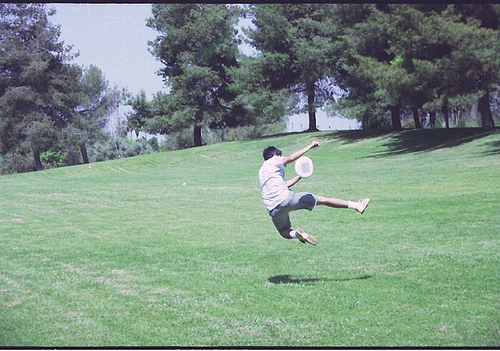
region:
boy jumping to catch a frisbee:
[255, 138, 372, 246]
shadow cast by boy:
[266, 270, 373, 285]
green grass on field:
[2, 130, 497, 348]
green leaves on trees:
[2, 4, 498, 170]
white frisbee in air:
[294, 153, 314, 180]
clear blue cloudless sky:
[2, 1, 354, 153]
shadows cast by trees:
[315, 129, 499, 161]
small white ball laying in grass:
[180, 178, 187, 186]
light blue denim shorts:
[265, 190, 317, 232]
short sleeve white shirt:
[258, 155, 290, 211]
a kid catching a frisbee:
[248, 135, 397, 268]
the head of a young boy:
[259, 139, 286, 164]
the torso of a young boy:
[251, 144, 294, 206]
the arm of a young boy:
[282, 138, 308, 165]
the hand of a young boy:
[302, 133, 327, 153]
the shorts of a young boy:
[255, 187, 312, 227]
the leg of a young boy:
[287, 191, 359, 225]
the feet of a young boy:
[352, 193, 374, 214]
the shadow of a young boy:
[249, 253, 365, 297]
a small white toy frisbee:
[288, 156, 315, 180]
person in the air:
[229, 144, 362, 261]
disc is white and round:
[283, 150, 320, 201]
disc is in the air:
[295, 154, 312, 181]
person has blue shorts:
[273, 198, 312, 236]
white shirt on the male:
[259, 159, 292, 204]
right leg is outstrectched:
[306, 189, 413, 239]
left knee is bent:
[271, 213, 315, 270]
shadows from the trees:
[318, 128, 493, 158]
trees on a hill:
[11, 69, 269, 144]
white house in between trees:
[276, 107, 362, 134]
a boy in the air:
[241, 120, 324, 175]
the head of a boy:
[254, 139, 289, 167]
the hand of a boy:
[306, 123, 334, 163]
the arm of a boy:
[273, 137, 322, 171]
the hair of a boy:
[262, 135, 289, 170]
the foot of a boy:
[331, 193, 382, 237]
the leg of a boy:
[291, 178, 387, 229]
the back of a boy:
[245, 138, 298, 234]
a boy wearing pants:
[268, 173, 335, 255]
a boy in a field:
[198, 116, 422, 288]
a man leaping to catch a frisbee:
[255, 133, 373, 240]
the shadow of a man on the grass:
[265, 269, 373, 287]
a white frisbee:
[293, 152, 316, 182]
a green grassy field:
[0, 126, 498, 347]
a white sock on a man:
[345, 199, 358, 210]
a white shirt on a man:
[258, 154, 293, 206]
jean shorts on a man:
[268, 188, 319, 236]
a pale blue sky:
[44, 3, 365, 131]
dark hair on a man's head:
[262, 146, 283, 159]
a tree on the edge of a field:
[150, 6, 248, 153]